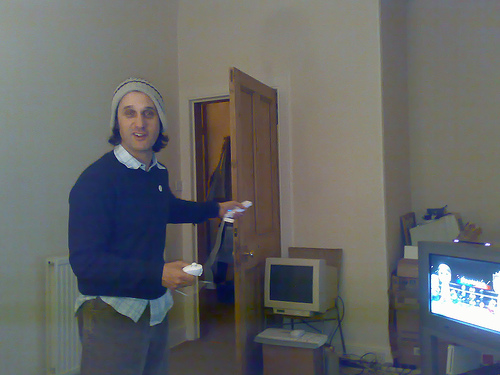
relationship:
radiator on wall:
[40, 251, 88, 374] [1, 0, 185, 374]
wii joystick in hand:
[182, 261, 203, 282] [159, 260, 207, 292]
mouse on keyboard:
[290, 327, 306, 339] [251, 324, 331, 352]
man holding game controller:
[57, 71, 245, 374] [224, 197, 258, 222]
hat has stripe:
[104, 78, 178, 138] [112, 81, 162, 99]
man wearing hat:
[57, 71, 245, 374] [104, 78, 178, 138]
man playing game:
[57, 71, 245, 374] [425, 248, 499, 333]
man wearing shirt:
[57, 71, 245, 374] [66, 140, 220, 302]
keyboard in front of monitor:
[251, 324, 331, 352] [262, 252, 342, 323]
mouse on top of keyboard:
[290, 327, 306, 339] [251, 324, 331, 352]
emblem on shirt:
[155, 180, 165, 193] [66, 140, 220, 302]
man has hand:
[57, 71, 245, 374] [159, 260, 207, 292]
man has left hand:
[57, 71, 245, 374] [215, 198, 249, 219]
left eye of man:
[139, 106, 156, 123] [57, 71, 245, 374]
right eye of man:
[122, 106, 139, 120] [57, 71, 245, 374]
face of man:
[116, 89, 160, 153] [57, 71, 245, 374]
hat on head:
[104, 78, 178, 138] [105, 76, 170, 165]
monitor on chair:
[262, 252, 342, 323] [261, 243, 351, 373]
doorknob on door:
[240, 249, 256, 264] [221, 62, 282, 374]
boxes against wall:
[387, 245, 453, 369] [379, 0, 499, 276]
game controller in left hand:
[224, 197, 258, 222] [215, 198, 249, 219]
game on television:
[425, 248, 499, 333] [415, 237, 499, 357]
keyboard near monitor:
[251, 324, 331, 352] [262, 252, 342, 323]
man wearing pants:
[57, 71, 245, 374] [70, 290, 171, 374]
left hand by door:
[215, 198, 249, 219] [221, 62, 282, 374]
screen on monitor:
[269, 265, 315, 305] [262, 252, 342, 323]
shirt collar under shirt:
[107, 142, 166, 176] [66, 140, 220, 302]